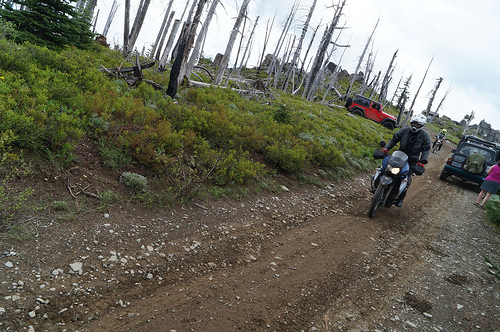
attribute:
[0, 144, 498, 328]
road — dirt 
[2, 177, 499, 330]
rocks — small, along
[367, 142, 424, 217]
motorcycle — blue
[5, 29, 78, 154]
bush — green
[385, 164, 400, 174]
headlight — on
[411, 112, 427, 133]
helmet — white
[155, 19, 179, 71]
trunk — tree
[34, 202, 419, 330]
dirt — brown, viisble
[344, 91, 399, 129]
jeep — red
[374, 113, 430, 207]
person — riding, riding motorcycle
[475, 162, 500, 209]
person — walking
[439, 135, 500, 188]
jeep — blue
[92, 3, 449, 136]
trees — dead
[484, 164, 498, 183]
top — purple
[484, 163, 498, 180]
shirt — pink